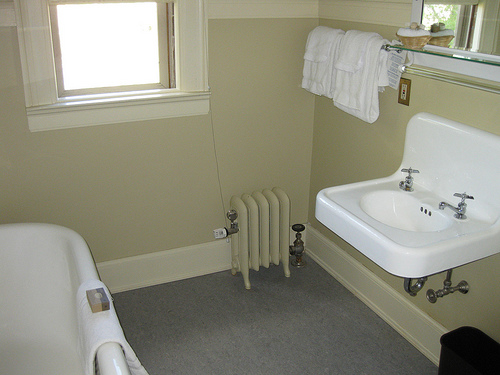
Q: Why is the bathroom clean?
A: No one is using it.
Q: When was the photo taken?
A: Daytime.